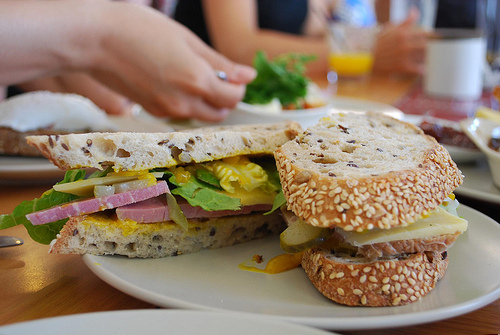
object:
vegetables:
[278, 215, 336, 254]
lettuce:
[0, 165, 112, 246]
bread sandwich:
[262, 109, 469, 309]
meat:
[113, 191, 274, 225]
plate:
[80, 203, 500, 334]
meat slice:
[24, 178, 171, 226]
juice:
[327, 52, 377, 83]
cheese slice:
[335, 205, 468, 247]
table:
[0, 180, 499, 334]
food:
[46, 210, 286, 261]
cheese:
[235, 249, 309, 276]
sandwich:
[0, 118, 304, 261]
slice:
[271, 111, 465, 234]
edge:
[271, 145, 464, 233]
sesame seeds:
[336, 286, 346, 297]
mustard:
[79, 212, 281, 256]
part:
[7, 276, 51, 304]